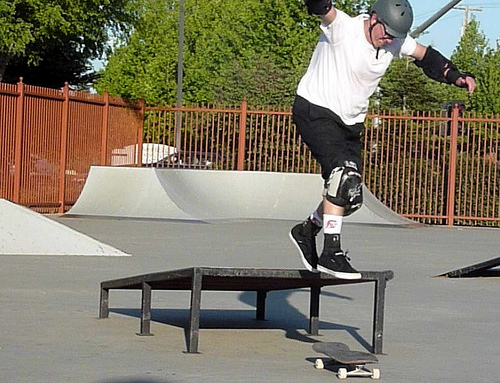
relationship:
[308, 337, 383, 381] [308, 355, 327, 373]
skateboard has wheel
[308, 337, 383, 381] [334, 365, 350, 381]
skateboard has wheel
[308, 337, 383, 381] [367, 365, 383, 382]
skateboard has wheel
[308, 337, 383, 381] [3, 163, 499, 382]
skateboard in park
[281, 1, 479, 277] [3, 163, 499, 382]
man in park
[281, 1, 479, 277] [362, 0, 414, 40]
man wearing helmet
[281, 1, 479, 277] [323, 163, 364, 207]
man wearing knee pads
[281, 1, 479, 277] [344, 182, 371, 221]
man wearing knee pads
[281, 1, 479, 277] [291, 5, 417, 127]
man wearing shirt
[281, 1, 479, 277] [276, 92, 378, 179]
man wearing shorts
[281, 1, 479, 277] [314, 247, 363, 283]
man wearing shoes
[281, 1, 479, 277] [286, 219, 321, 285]
man wearing shoes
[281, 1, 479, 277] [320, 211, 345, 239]
man wearing socks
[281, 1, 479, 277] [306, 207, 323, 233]
man wearing socks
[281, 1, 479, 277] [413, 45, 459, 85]
man wearing arm pads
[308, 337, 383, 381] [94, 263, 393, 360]
skateboard near ramp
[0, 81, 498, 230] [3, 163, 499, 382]
fence surrounds park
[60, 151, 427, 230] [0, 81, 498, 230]
ramp near fence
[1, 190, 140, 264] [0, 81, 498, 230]
ramp near fence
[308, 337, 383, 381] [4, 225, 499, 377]
skateboard on ground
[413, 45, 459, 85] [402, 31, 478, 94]
elbow pad on arm